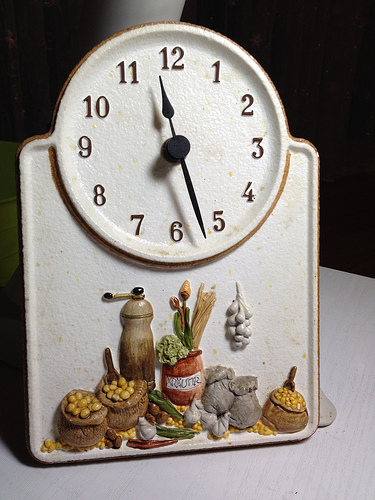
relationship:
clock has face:
[46, 50, 261, 185] [83, 50, 284, 242]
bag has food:
[262, 397, 320, 435] [274, 388, 307, 411]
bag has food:
[96, 375, 149, 431] [103, 377, 135, 401]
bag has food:
[52, 399, 105, 450] [66, 392, 102, 418]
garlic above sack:
[227, 279, 251, 351] [206, 368, 235, 413]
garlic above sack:
[227, 279, 251, 351] [228, 366, 257, 432]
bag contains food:
[57, 388, 108, 446] [268, 389, 308, 415]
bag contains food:
[97, 376, 145, 425] [105, 374, 129, 409]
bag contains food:
[260, 389, 309, 433] [68, 393, 102, 413]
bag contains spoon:
[57, 388, 108, 446] [280, 366, 301, 387]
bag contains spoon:
[97, 376, 145, 425] [280, 366, 301, 387]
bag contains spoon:
[260, 389, 309, 433] [280, 366, 301, 387]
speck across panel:
[221, 168, 233, 179] [17, 137, 320, 465]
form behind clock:
[2, 3, 374, 278] [14, 21, 339, 469]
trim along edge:
[277, 148, 291, 201] [18, 164, 44, 449]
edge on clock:
[18, 164, 44, 449] [54, 23, 282, 268]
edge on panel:
[18, 164, 44, 449] [21, 150, 317, 444]